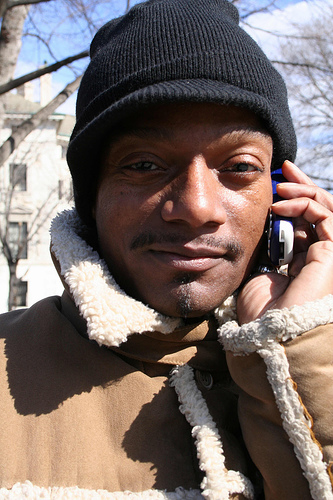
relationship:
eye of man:
[122, 156, 171, 178] [3, 1, 330, 498]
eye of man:
[220, 154, 265, 178] [3, 1, 330, 498]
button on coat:
[193, 365, 219, 392] [4, 260, 329, 496]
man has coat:
[3, 1, 330, 498] [4, 260, 329, 496]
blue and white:
[269, 219, 279, 258] [279, 223, 292, 263]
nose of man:
[165, 152, 223, 231] [3, 1, 330, 498]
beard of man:
[145, 267, 235, 318] [3, 1, 330, 498]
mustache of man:
[127, 228, 249, 258] [3, 1, 330, 498]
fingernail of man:
[282, 155, 299, 175] [3, 1, 330, 498]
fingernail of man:
[272, 181, 296, 191] [3, 1, 330, 498]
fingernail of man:
[271, 196, 291, 214] [3, 1, 330, 498]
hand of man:
[234, 159, 332, 320] [3, 1, 330, 498]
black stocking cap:
[141, 20, 188, 42] [73, 0, 300, 154]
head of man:
[67, 0, 287, 310] [3, 1, 330, 498]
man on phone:
[3, 1, 330, 498] [267, 165, 294, 265]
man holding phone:
[3, 1, 330, 498] [267, 165, 294, 265]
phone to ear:
[267, 165, 294, 265] [269, 158, 285, 225]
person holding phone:
[3, 1, 330, 498] [267, 165, 294, 265]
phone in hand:
[267, 165, 294, 265] [234, 159, 332, 320]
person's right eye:
[3, 1, 330, 498] [122, 156, 171, 178]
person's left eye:
[3, 1, 330, 498] [220, 154, 265, 178]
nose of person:
[165, 152, 223, 231] [3, 1, 330, 498]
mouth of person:
[148, 243, 238, 279] [3, 1, 330, 498]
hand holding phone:
[234, 159, 332, 320] [267, 165, 294, 265]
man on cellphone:
[3, 1, 330, 498] [267, 165, 294, 265]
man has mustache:
[3, 1, 330, 498] [127, 228, 249, 258]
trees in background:
[273, 2, 333, 162] [5, 2, 332, 137]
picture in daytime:
[3, 1, 330, 498] [285, 2, 331, 166]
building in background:
[2, 64, 66, 289] [5, 2, 332, 137]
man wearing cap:
[3, 1, 330, 498] [73, 0, 300, 154]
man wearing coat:
[3, 1, 330, 498] [4, 260, 329, 496]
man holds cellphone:
[3, 1, 330, 498] [267, 165, 294, 265]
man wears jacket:
[3, 1, 330, 498] [4, 260, 329, 496]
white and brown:
[86, 287, 126, 332] [61, 408, 114, 445]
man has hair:
[3, 1, 330, 498] [127, 228, 249, 258]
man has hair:
[3, 1, 330, 498] [169, 275, 194, 316]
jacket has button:
[4, 260, 329, 496] [193, 365, 219, 392]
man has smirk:
[3, 1, 330, 498] [122, 223, 248, 293]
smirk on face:
[122, 223, 248, 293] [67, 0, 287, 310]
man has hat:
[3, 1, 330, 498] [73, 0, 300, 154]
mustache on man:
[127, 228, 249, 258] [3, 1, 330, 498]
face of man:
[67, 0, 287, 310] [3, 1, 330, 498]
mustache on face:
[127, 228, 249, 258] [95, 104, 273, 305]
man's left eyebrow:
[3, 1, 330, 498] [217, 126, 269, 154]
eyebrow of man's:
[217, 126, 269, 154] [3, 1, 330, 498]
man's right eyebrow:
[3, 1, 330, 498] [112, 120, 172, 149]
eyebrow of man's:
[112, 120, 172, 149] [3, 1, 330, 498]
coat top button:
[4, 260, 329, 496] [193, 365, 219, 392]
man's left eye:
[3, 1, 330, 498] [220, 154, 265, 178]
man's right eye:
[3, 1, 330, 498] [122, 156, 171, 178]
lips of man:
[148, 243, 238, 279] [3, 1, 330, 498]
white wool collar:
[86, 287, 126, 332] [49, 215, 244, 342]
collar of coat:
[49, 215, 244, 342] [4, 260, 329, 496]